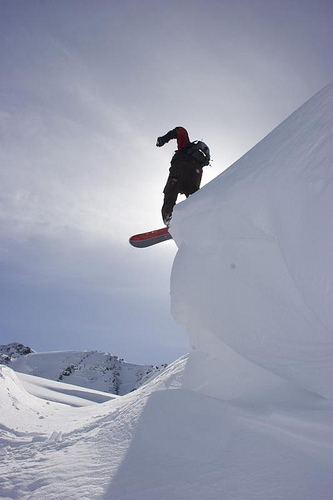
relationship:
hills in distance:
[2, 338, 176, 408] [4, 192, 318, 424]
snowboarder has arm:
[119, 117, 219, 257] [150, 120, 192, 161]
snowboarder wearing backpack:
[119, 117, 219, 257] [172, 138, 201, 192]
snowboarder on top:
[119, 117, 219, 257] [128, 66, 332, 217]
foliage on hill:
[54, 351, 133, 396] [13, 345, 171, 400]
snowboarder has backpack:
[119, 117, 219, 257] [172, 138, 201, 192]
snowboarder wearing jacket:
[119, 117, 219, 257] [154, 123, 225, 190]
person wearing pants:
[123, 125, 226, 263] [161, 176, 201, 229]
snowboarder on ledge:
[119, 117, 219, 257] [165, 190, 222, 239]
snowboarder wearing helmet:
[119, 117, 219, 257] [195, 140, 208, 154]